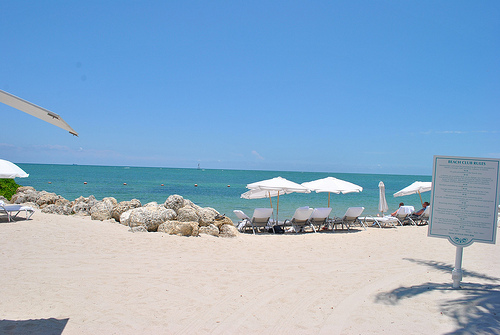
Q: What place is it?
A: It is a beach.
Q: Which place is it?
A: It is a beach.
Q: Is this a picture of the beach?
A: Yes, it is showing the beach.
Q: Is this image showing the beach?
A: Yes, it is showing the beach.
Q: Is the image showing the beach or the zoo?
A: It is showing the beach.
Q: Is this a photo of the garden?
A: No, the picture is showing the beach.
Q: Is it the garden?
A: No, it is the beach.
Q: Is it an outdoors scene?
A: Yes, it is outdoors.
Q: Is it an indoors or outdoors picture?
A: It is outdoors.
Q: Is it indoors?
A: No, it is outdoors.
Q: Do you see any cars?
A: No, there are no cars.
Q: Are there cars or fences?
A: No, there are no cars or fences.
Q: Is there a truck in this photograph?
A: Yes, there is a truck.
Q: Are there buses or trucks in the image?
A: Yes, there is a truck.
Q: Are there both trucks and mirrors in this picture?
A: No, there is a truck but no mirrors.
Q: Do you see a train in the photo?
A: No, there are no trains.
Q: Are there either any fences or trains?
A: No, there are no trains or fences.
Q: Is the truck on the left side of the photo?
A: Yes, the truck is on the left of the image.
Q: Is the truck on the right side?
A: No, the truck is on the left of the image.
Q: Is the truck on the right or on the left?
A: The truck is on the left of the image.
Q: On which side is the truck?
A: The truck is on the left of the image.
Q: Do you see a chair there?
A: Yes, there is a chair.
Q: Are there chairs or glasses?
A: Yes, there is a chair.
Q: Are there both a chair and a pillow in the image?
A: No, there is a chair but no pillows.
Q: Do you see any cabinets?
A: No, there are no cabinets.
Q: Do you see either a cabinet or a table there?
A: No, there are no cabinets or tables.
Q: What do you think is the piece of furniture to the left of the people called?
A: The piece of furniture is a chair.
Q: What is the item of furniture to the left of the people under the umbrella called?
A: The piece of furniture is a chair.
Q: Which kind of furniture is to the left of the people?
A: The piece of furniture is a chair.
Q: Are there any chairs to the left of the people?
A: Yes, there is a chair to the left of the people.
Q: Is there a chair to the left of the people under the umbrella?
A: Yes, there is a chair to the left of the people.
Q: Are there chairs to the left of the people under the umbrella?
A: Yes, there is a chair to the left of the people.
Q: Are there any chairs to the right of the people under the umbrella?
A: No, the chair is to the left of the people.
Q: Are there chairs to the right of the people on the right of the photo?
A: No, the chair is to the left of the people.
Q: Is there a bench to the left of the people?
A: No, there is a chair to the left of the people.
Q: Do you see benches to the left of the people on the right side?
A: No, there is a chair to the left of the people.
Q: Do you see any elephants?
A: No, there are no elephants.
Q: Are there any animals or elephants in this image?
A: No, there are no elephants or animals.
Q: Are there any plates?
A: No, there are no plates.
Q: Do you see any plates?
A: No, there are no plates.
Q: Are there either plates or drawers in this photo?
A: No, there are no plates or drawers.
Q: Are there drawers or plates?
A: No, there are no plates or drawers.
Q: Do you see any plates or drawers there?
A: No, there are no plates or drawers.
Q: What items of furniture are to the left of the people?
A: The pieces of furniture are chairs.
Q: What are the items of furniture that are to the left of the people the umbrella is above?
A: The pieces of furniture are chairs.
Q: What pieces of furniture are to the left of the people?
A: The pieces of furniture are chairs.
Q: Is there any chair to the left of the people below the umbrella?
A: Yes, there are chairs to the left of the people.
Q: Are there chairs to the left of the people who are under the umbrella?
A: Yes, there are chairs to the left of the people.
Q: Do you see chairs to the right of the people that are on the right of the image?
A: No, the chairs are to the left of the people.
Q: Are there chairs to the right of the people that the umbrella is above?
A: No, the chairs are to the left of the people.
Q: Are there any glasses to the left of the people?
A: No, there are chairs to the left of the people.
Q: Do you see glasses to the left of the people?
A: No, there are chairs to the left of the people.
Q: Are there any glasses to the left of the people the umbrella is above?
A: No, there are chairs to the left of the people.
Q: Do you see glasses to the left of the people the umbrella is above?
A: No, there are chairs to the left of the people.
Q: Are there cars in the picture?
A: No, there are no cars.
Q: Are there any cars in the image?
A: No, there are no cars.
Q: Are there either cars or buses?
A: No, there are no cars or buses.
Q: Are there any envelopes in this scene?
A: No, there are no envelopes.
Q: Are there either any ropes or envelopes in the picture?
A: No, there are no envelopes or ropes.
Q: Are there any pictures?
A: No, there are no pictures.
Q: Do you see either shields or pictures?
A: No, there are no pictures or shields.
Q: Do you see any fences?
A: No, there are no fences.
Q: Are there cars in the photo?
A: No, there are no cars.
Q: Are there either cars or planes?
A: No, there are no cars or planes.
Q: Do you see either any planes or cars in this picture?
A: No, there are no cars or planes.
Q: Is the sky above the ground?
A: Yes, the sky is above the ground.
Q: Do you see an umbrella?
A: Yes, there is an umbrella.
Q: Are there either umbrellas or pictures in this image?
A: Yes, there is an umbrella.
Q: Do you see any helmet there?
A: No, there are no helmets.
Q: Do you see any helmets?
A: No, there are no helmets.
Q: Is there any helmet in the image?
A: No, there are no helmets.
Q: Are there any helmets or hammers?
A: No, there are no helmets or hammers.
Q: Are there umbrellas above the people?
A: Yes, there is an umbrella above the people.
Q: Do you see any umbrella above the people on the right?
A: Yes, there is an umbrella above the people.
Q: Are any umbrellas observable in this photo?
A: Yes, there are umbrellas.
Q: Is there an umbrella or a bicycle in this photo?
A: Yes, there are umbrellas.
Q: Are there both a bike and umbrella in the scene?
A: No, there are umbrellas but no bikes.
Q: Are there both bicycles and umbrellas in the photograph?
A: No, there are umbrellas but no bikes.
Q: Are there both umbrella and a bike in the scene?
A: No, there are umbrellas but no bikes.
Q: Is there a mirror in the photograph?
A: No, there are no mirrors.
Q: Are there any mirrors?
A: No, there are no mirrors.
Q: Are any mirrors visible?
A: No, there are no mirrors.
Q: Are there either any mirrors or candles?
A: No, there are no mirrors or candles.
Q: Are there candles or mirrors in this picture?
A: No, there are no mirrors or candles.